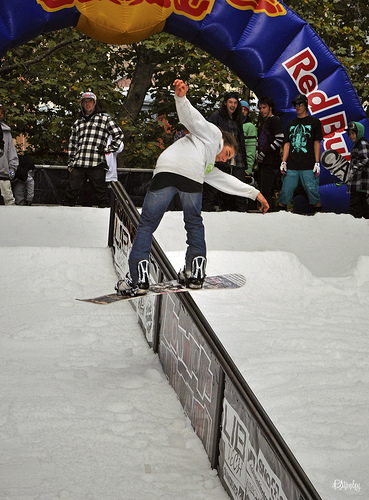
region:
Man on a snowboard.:
[64, 63, 270, 328]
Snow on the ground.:
[57, 339, 178, 489]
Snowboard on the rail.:
[87, 249, 291, 324]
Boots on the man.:
[84, 220, 220, 305]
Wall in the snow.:
[154, 275, 262, 495]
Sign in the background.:
[238, 13, 357, 128]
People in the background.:
[196, 57, 334, 218]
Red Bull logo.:
[280, 33, 366, 209]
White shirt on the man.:
[158, 83, 314, 234]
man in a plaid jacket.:
[65, 82, 138, 194]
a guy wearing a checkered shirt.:
[74, 114, 110, 185]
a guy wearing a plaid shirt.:
[68, 110, 119, 203]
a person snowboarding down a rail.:
[159, 81, 254, 368]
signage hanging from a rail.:
[159, 300, 286, 485]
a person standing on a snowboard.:
[110, 252, 283, 311]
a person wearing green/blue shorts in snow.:
[285, 155, 329, 226]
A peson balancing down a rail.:
[148, 78, 221, 297]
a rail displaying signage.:
[157, 297, 248, 452]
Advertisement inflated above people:
[35, 2, 368, 95]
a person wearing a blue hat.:
[240, 96, 250, 116]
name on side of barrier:
[218, 420, 268, 482]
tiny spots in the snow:
[99, 402, 149, 427]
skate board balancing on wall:
[80, 256, 246, 297]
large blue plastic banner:
[198, 12, 337, 112]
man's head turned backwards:
[205, 118, 244, 170]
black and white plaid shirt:
[65, 113, 128, 169]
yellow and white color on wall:
[15, 130, 38, 146]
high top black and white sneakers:
[124, 257, 150, 292]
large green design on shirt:
[285, 123, 320, 157]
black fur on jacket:
[213, 95, 254, 123]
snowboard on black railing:
[69, 262, 251, 309]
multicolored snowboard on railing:
[78, 271, 244, 308]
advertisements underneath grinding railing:
[101, 200, 312, 498]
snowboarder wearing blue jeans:
[128, 174, 222, 287]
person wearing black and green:
[283, 95, 323, 220]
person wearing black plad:
[63, 89, 119, 199]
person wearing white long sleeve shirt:
[148, 89, 258, 210]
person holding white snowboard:
[319, 117, 367, 208]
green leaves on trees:
[14, 34, 236, 164]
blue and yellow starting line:
[1, 0, 358, 224]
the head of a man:
[195, 118, 286, 165]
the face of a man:
[207, 120, 248, 173]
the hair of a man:
[206, 109, 277, 174]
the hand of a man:
[152, 61, 212, 110]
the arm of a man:
[159, 76, 233, 232]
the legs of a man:
[123, 166, 247, 308]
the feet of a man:
[96, 242, 234, 317]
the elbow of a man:
[166, 107, 198, 142]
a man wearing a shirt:
[85, 86, 244, 298]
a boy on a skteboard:
[62, 115, 286, 359]